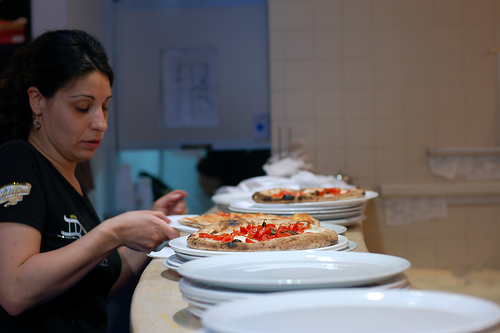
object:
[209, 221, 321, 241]
toppings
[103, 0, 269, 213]
wall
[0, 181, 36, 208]
logo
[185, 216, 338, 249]
pizza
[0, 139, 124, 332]
shirt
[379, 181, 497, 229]
restaurant orders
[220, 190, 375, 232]
stack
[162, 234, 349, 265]
stack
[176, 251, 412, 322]
stack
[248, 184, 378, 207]
plate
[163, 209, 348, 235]
plate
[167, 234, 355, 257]
plate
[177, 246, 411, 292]
plate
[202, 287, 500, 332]
plate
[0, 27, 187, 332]
girl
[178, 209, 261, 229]
pizza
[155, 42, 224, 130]
paper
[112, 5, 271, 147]
cabinet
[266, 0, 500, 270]
wall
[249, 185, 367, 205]
pizza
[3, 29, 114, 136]
hair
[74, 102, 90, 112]
eye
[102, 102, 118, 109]
eye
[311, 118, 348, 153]
tile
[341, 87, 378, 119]
tile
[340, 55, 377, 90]
tile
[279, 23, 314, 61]
tile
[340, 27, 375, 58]
tile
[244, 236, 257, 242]
food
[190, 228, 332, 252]
crust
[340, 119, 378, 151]
tile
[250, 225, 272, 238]
tomatoes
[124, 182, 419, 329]
counter